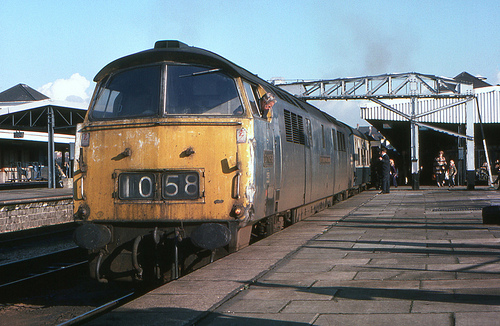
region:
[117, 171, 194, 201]
number on the front of the train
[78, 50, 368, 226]
an old train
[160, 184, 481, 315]
a brick train platform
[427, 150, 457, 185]
people walking on the platform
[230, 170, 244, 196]
a metal handle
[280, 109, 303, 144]
vent on the side of the train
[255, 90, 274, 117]
man is looking out the window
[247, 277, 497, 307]
a person's shadow on the ground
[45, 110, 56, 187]
a steel support beam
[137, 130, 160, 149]
white marks on the train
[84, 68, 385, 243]
silver and yellow train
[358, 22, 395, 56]
white clouds in blue sky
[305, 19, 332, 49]
white clouds in blue sky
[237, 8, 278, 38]
white clouds in blue sky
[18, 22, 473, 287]
A train is on the railroad tracks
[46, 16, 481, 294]
A train is picking up passengers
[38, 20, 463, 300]
The train has some numbers in front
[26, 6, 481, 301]
The train is traveling in the sunshine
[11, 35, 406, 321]
The train is on time today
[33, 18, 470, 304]
The train is owned by the railroad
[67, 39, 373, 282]
Old yellow and silver train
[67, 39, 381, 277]
Train at a train station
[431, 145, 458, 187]
Woman and child at a train station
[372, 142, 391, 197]
Man dressed in a black suit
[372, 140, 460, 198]
Four people at a train station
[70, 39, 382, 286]
Train on train tracks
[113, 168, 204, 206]
White numbers on the front of a train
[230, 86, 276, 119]
Man sticking his head out of a train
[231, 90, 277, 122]
Conductor sticking his head out of the window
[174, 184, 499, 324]
Concrete brick pathway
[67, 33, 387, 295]
train on train tracks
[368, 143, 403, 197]
person standing on platform outside of train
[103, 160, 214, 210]
black and white number on front of train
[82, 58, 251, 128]
windshields on front of train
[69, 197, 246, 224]
two yellow lights on front of train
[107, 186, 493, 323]
stone platform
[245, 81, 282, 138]
person looking out of window of train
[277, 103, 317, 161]
grate on side of train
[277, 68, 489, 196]
metal rail structure over train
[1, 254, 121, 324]
train tracks on ground